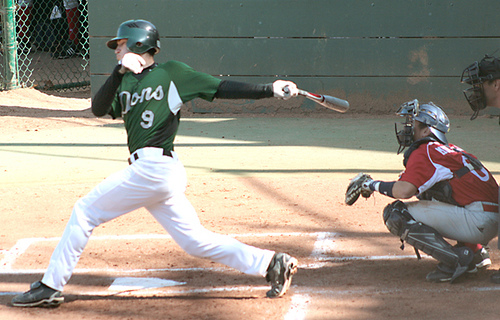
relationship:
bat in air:
[281, 86, 350, 114] [5, 8, 459, 97]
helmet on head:
[399, 97, 446, 143] [103, 14, 170, 57]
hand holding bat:
[268, 79, 294, 101] [284, 80, 351, 112]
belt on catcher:
[458, 189, 498, 224] [306, 72, 493, 289]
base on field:
[104, 264, 189, 301] [93, 69, 294, 198]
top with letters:
[94, 50, 228, 153] [113, 85, 175, 120]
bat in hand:
[281, 72, 358, 121] [266, 75, 308, 107]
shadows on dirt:
[193, 105, 408, 185] [0, 100, 498, 303]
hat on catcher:
[394, 90, 465, 139] [339, 100, 500, 285]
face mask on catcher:
[387, 96, 427, 159] [339, 100, 500, 285]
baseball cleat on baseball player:
[263, 250, 300, 299] [6, 15, 352, 309]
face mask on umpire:
[459, 60, 488, 113] [451, 53, 498, 118]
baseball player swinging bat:
[6, 18, 299, 308] [283, 85, 349, 115]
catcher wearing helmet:
[339, 100, 500, 285] [393, 92, 458, 153]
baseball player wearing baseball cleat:
[6, 18, 299, 308] [256, 239, 300, 304]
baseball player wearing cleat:
[6, 18, 299, 308] [5, 279, 69, 309]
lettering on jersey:
[113, 84, 170, 116] [106, 58, 223, 147]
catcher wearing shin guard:
[339, 100, 500, 285] [382, 199, 459, 274]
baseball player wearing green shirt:
[6, 18, 299, 308] [87, 57, 240, 159]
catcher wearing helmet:
[339, 100, 496, 288] [400, 90, 451, 145]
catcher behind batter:
[339, 100, 500, 285] [9, 15, 355, 301]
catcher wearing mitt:
[339, 100, 496, 288] [336, 171, 375, 207]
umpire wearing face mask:
[459, 51, 497, 122] [459, 62, 486, 112]